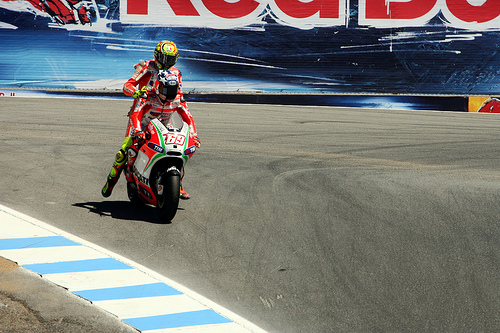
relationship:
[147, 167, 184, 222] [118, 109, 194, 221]
tire of a motorcycle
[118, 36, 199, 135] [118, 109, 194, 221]
people riding a motorcycle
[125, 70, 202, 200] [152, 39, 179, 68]
people wearing helmet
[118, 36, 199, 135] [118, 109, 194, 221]
men riding on motorcycle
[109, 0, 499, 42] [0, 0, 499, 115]
advertisement across a advertisement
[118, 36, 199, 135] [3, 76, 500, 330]
people racing on a race track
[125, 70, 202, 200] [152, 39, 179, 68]
people wearing a helmet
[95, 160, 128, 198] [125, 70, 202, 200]
boot of a people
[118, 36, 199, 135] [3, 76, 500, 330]
people riding on a race track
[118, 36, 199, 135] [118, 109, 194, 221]
people sitting on a motorcycle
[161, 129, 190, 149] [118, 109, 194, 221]
number 69 across a motorcycle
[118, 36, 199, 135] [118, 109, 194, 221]
people using a motorcycle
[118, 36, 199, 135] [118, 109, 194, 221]
people operating a motorcycle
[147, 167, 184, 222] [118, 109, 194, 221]
tire attached to a motorcycle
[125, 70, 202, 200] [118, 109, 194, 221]
people riding a motorcycle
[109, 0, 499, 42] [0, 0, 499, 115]
advertisement across advertisement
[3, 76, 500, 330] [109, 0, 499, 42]
race track near a advertisement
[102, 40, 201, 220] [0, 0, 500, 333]
picture taken picture